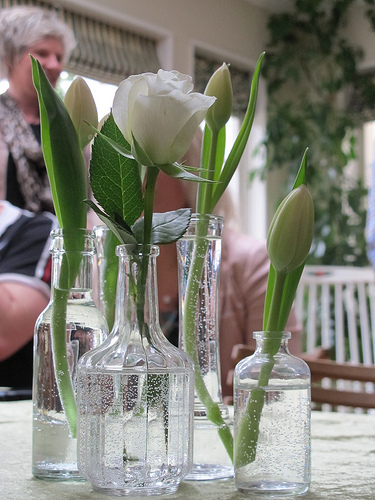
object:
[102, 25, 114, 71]
blinds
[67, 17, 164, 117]
window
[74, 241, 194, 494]
clear vase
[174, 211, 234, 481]
clear vase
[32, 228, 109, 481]
clear vase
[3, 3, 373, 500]
room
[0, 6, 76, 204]
person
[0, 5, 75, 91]
head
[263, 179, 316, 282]
flower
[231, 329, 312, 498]
clear jar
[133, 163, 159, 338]
stem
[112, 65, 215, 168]
flower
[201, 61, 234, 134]
flower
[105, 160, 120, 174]
veins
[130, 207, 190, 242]
leaf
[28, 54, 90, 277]
leaf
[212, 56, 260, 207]
leaf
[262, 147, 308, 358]
leaf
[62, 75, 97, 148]
rose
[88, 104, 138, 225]
green leaf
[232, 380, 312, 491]
water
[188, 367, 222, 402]
water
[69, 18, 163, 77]
curtain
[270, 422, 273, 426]
bubbles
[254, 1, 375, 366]
plant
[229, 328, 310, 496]
bottles